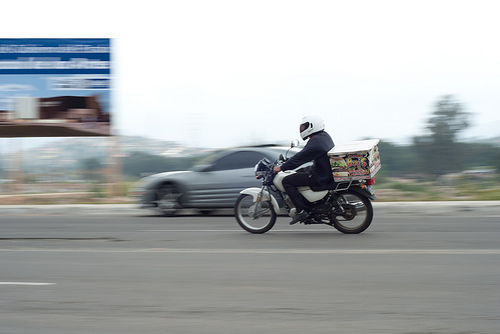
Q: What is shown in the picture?
A: A street.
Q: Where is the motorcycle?
A: On the inside lane.